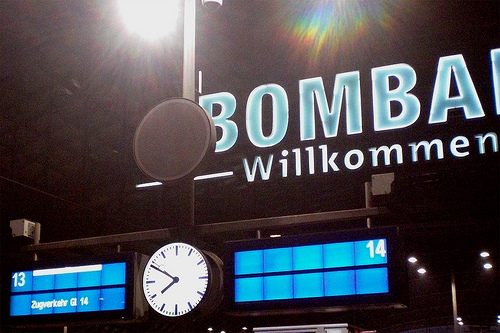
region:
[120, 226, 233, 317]
this is a clock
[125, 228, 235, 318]
white face on clock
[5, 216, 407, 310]
blue screens next to clock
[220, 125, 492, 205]
set of suspended letters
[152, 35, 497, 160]
set of blue suspend letters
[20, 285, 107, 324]
white writing on sign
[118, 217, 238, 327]
this is a clcock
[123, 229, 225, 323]
white face on clock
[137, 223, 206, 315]
black hand on clock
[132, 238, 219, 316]
black ticks on clock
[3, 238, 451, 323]
blue screens next to clock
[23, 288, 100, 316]
white letters on sign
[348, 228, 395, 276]
white number on sign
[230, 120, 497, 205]
a white suspended light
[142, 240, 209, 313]
A round white clock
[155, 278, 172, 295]
An hour hand on a clock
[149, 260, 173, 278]
Minute hand on a clock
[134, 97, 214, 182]
A round object above a clock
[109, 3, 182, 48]
A bright light above a pole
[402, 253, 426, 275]
Lights in a ceiling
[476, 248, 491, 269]
Lights in a ceiling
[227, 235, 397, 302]
Blue window in front of building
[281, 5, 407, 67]
Bright colored lights in the air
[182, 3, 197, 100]
A pole with a light on it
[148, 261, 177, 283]
clock with a black minute hand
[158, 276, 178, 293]
clock with a black hour hand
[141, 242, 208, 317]
clock has a white face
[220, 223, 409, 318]
sign has a white number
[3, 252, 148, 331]
sign has a white number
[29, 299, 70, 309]
sign has white lettering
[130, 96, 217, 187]
black circle above clock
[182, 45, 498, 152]
blue lettering above the sign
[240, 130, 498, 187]
white lettering above the sign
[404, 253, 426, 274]
lights behind the sign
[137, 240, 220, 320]
black and white clock on black pole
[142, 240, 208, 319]
black time lines on clock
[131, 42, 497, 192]
blue lit sign on front of building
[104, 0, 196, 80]
white light on ceiling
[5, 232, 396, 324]
blue digital window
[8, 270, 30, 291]
number on blue digital window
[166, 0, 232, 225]
metal pole with camera on top of it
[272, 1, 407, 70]
light reflected in air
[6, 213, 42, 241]
tan box on top of metal structure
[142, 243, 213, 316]
big white clock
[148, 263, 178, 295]
black hands of white clock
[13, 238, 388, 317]
blue screen at both sides of clock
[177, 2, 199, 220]
large grey post above clock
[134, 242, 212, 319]
clock is a bright white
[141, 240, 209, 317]
black and white clock in the center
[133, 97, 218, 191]
black circle in pole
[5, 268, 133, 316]
bright blue left screen on the wall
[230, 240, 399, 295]
bright blue right screen on the wall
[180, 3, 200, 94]
light gray pole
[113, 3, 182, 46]
flash of white light top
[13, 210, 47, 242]
box brown metal beam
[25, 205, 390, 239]
brown metal rod top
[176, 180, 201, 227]
lower post of black light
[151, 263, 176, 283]
small black clock timer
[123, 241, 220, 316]
The face of the clock is white.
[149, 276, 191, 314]
The time numbers on the clock are black.